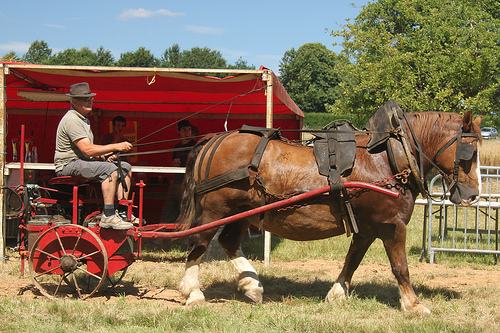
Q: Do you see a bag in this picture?
A: No, there are no bags.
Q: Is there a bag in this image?
A: No, there are no bags.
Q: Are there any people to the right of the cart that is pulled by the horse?
A: Yes, there are people to the right of the cart.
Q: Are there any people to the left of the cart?
A: No, the people are to the right of the cart.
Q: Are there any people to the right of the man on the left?
A: Yes, there are people to the right of the man.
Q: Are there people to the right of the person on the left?
A: Yes, there are people to the right of the man.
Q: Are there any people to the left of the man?
A: No, the people are to the right of the man.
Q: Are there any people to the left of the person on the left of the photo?
A: No, the people are to the right of the man.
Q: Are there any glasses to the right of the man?
A: No, there are people to the right of the man.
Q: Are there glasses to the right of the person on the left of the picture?
A: No, there are people to the right of the man.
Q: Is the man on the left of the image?
A: Yes, the man is on the left of the image.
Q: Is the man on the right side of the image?
A: No, the man is on the left of the image.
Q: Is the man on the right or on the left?
A: The man is on the left of the image.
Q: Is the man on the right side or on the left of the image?
A: The man is on the left of the image.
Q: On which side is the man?
A: The man is on the left of the image.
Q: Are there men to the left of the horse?
A: Yes, there is a man to the left of the horse.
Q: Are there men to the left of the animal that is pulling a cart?
A: Yes, there is a man to the left of the horse.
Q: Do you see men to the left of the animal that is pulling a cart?
A: Yes, there is a man to the left of the horse.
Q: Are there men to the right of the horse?
A: No, the man is to the left of the horse.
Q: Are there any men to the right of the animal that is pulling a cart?
A: No, the man is to the left of the horse.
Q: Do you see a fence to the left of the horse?
A: No, there is a man to the left of the horse.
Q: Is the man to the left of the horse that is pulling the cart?
A: Yes, the man is to the left of the horse.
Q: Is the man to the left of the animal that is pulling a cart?
A: Yes, the man is to the left of the horse.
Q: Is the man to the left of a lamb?
A: No, the man is to the left of the horse.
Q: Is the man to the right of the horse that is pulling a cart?
A: No, the man is to the left of the horse.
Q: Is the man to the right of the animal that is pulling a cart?
A: No, the man is to the left of the horse.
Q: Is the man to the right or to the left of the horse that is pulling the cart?
A: The man is to the left of the horse.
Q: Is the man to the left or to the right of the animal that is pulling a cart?
A: The man is to the left of the horse.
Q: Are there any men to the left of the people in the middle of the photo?
A: Yes, there is a man to the left of the people.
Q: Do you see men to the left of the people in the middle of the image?
A: Yes, there is a man to the left of the people.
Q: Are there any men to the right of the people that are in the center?
A: No, the man is to the left of the people.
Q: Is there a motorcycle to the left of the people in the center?
A: No, there is a man to the left of the people.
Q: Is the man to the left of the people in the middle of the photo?
A: Yes, the man is to the left of the people.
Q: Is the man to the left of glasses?
A: No, the man is to the left of the people.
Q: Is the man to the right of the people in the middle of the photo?
A: No, the man is to the left of the people.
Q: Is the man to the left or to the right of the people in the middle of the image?
A: The man is to the left of the people.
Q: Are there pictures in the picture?
A: No, there are no pictures.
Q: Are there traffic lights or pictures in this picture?
A: No, there are no pictures or traffic lights.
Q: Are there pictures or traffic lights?
A: No, there are no pictures or traffic lights.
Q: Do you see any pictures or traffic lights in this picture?
A: No, there are no pictures or traffic lights.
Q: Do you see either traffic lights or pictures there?
A: No, there are no pictures or traffic lights.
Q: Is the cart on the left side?
A: Yes, the cart is on the left of the image.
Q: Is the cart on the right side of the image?
A: No, the cart is on the left of the image.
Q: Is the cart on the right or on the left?
A: The cart is on the left of the image.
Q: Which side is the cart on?
A: The cart is on the left of the image.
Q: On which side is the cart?
A: The cart is on the left of the image.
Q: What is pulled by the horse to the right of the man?
A: The cart is pulled by the horse.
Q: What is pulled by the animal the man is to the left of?
A: The cart is pulled by the horse.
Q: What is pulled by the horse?
A: The cart is pulled by the horse.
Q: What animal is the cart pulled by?
A: The cart is pulled by the horse.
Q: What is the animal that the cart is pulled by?
A: The animal is a horse.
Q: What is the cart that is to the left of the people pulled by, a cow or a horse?
A: The cart is pulled by a horse.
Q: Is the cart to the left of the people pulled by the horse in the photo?
A: Yes, the cart is pulled by the horse.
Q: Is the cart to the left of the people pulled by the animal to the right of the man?
A: Yes, the cart is pulled by the horse.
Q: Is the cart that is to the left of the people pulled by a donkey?
A: No, the cart is pulled by the horse.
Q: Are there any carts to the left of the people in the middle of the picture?
A: Yes, there is a cart to the left of the people.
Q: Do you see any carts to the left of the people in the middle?
A: Yes, there is a cart to the left of the people.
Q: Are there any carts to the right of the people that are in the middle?
A: No, the cart is to the left of the people.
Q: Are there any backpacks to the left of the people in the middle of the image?
A: No, there is a cart to the left of the people.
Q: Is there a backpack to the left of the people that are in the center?
A: No, there is a cart to the left of the people.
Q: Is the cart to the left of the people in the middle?
A: Yes, the cart is to the left of the people.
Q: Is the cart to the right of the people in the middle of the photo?
A: No, the cart is to the left of the people.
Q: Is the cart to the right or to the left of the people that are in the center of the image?
A: The cart is to the left of the people.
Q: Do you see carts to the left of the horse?
A: Yes, there is a cart to the left of the horse.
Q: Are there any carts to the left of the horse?
A: Yes, there is a cart to the left of the horse.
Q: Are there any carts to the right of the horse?
A: No, the cart is to the left of the horse.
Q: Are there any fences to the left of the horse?
A: No, there is a cart to the left of the horse.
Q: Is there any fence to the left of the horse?
A: No, there is a cart to the left of the horse.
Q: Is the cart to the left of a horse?
A: Yes, the cart is to the left of a horse.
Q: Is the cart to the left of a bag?
A: No, the cart is to the left of a horse.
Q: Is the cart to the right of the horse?
A: No, the cart is to the left of the horse.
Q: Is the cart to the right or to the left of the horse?
A: The cart is to the left of the horse.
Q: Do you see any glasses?
A: No, there are no glasses.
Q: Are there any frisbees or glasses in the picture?
A: No, there are no glasses or frisbees.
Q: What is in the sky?
A: The clouds are in the sky.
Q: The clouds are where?
A: The clouds are in the sky.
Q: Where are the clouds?
A: The clouds are in the sky.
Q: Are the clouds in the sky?
A: Yes, the clouds are in the sky.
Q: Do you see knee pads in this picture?
A: No, there are no knee pads.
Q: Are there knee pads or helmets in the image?
A: No, there are no knee pads or helmets.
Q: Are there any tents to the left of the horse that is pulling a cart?
A: Yes, there is a tent to the left of the horse.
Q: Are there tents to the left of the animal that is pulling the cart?
A: Yes, there is a tent to the left of the horse.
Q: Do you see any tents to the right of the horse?
A: No, the tent is to the left of the horse.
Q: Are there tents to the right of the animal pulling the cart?
A: No, the tent is to the left of the horse.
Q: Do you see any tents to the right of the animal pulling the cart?
A: No, the tent is to the left of the horse.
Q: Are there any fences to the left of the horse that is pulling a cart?
A: No, there is a tent to the left of the horse.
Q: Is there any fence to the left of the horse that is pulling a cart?
A: No, there is a tent to the left of the horse.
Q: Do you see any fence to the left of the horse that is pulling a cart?
A: No, there is a tent to the left of the horse.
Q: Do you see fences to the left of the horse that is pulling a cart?
A: No, there is a tent to the left of the horse.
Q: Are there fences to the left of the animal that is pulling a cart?
A: No, there is a tent to the left of the horse.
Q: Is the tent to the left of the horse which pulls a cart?
A: Yes, the tent is to the left of the horse.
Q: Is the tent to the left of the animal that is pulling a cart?
A: Yes, the tent is to the left of the horse.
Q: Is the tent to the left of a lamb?
A: No, the tent is to the left of the horse.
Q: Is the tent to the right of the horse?
A: No, the tent is to the left of the horse.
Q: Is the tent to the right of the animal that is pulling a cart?
A: No, the tent is to the left of the horse.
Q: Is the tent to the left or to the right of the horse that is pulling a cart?
A: The tent is to the left of the horse.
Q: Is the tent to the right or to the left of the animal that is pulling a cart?
A: The tent is to the left of the horse.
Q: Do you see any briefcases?
A: No, there are no briefcases.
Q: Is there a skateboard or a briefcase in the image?
A: No, there are no briefcases or skateboards.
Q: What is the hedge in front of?
A: The hedge is in front of the trees.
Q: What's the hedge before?
A: The hedge is in front of the trees.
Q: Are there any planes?
A: No, there are no planes.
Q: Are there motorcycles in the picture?
A: No, there are no motorcycles.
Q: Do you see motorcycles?
A: No, there are no motorcycles.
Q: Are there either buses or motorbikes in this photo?
A: No, there are no motorbikes or buses.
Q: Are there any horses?
A: Yes, there is a horse.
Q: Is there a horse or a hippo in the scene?
A: Yes, there is a horse.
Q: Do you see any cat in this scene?
A: No, there are no cats.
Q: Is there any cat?
A: No, there are no cats.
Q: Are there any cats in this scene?
A: No, there are no cats.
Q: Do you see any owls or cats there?
A: No, there are no cats or owls.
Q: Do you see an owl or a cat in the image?
A: No, there are no cats or owls.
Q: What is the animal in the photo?
A: The animal is a horse.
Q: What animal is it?
A: The animal is a horse.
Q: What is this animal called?
A: This is a horse.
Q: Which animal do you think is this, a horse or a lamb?
A: This is a horse.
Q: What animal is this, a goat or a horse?
A: This is a horse.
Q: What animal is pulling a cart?
A: The horse is pulling a cart.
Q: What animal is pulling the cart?
A: The horse is pulling a cart.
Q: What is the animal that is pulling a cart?
A: The animal is a horse.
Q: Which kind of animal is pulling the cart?
A: The animal is a horse.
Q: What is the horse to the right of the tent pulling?
A: The horse is pulling a cart.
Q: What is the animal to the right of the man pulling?
A: The horse is pulling a cart.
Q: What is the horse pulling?
A: The horse is pulling a cart.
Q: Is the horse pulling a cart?
A: Yes, the horse is pulling a cart.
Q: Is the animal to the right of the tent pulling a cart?
A: Yes, the horse is pulling a cart.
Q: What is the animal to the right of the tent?
A: The animal is a horse.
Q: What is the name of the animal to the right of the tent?
A: The animal is a horse.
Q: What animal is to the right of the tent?
A: The animal is a horse.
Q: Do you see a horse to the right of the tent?
A: Yes, there is a horse to the right of the tent.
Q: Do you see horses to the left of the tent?
A: No, the horse is to the right of the tent.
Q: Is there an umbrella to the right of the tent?
A: No, there is a horse to the right of the tent.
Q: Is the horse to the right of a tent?
A: Yes, the horse is to the right of a tent.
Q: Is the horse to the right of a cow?
A: No, the horse is to the right of a tent.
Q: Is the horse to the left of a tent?
A: No, the horse is to the right of a tent.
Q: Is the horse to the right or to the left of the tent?
A: The horse is to the right of the tent.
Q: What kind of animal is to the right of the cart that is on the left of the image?
A: The animal is a horse.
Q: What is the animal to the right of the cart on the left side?
A: The animal is a horse.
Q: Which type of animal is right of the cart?
A: The animal is a horse.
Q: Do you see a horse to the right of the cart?
A: Yes, there is a horse to the right of the cart.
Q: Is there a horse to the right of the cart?
A: Yes, there is a horse to the right of the cart.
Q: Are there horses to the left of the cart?
A: No, the horse is to the right of the cart.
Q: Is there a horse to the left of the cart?
A: No, the horse is to the right of the cart.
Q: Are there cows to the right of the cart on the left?
A: No, there is a horse to the right of the cart.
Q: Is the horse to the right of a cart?
A: Yes, the horse is to the right of a cart.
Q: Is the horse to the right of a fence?
A: No, the horse is to the right of a cart.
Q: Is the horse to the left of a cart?
A: No, the horse is to the right of a cart.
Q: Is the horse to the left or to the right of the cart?
A: The horse is to the right of the cart.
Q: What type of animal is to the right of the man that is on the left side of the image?
A: The animal is a horse.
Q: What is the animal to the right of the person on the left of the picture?
A: The animal is a horse.